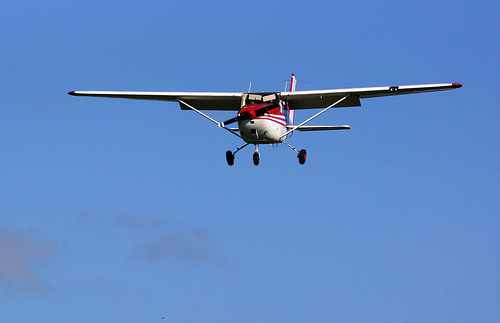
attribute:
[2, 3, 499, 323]
airplane — flying, mostly white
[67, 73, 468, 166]
airplane — red, blue, white, small engine, in air, flying in air, flying in sky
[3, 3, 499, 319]
sky — blue, clear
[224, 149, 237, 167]
wheel — black, for landing, on the side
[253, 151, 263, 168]
wheel — black, for landing, in the middle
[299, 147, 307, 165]
wheel — for landing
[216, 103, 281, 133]
propeller — black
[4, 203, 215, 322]
cloud — dark, wispy, grey, white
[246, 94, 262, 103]
window — for pilot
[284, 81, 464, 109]
wing — silver, white, long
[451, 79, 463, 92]
tip — red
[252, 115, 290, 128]
stripe — red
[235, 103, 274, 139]
nose — red, silver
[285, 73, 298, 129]
tail — silver, red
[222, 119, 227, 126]
stripe — white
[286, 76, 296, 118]
stripe — red